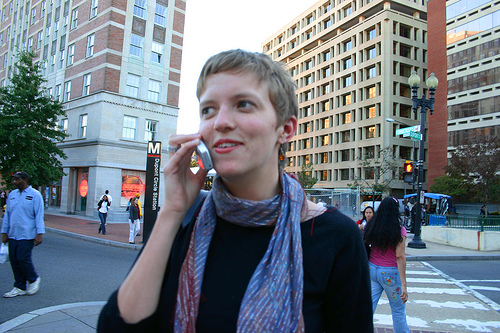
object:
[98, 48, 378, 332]
girl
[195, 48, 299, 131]
hair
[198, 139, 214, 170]
phone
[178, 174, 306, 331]
scarf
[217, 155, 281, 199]
neck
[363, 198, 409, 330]
woman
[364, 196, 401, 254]
hair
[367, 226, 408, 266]
shirt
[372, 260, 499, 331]
crosswalk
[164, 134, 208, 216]
hand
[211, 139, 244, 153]
mouth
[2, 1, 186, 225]
building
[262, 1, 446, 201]
building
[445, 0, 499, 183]
building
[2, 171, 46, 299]
man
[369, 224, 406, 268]
pink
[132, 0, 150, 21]
windows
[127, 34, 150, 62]
windows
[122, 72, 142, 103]
windows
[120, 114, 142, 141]
windows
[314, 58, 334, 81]
windows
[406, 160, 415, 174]
don't walk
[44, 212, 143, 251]
corner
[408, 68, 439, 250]
street light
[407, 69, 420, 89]
globe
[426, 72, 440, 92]
globe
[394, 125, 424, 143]
signs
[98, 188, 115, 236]
people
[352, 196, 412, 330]
people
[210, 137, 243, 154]
lipstick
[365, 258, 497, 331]
street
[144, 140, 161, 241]
pole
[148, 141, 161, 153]
m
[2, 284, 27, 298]
tennis shoes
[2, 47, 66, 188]
tree